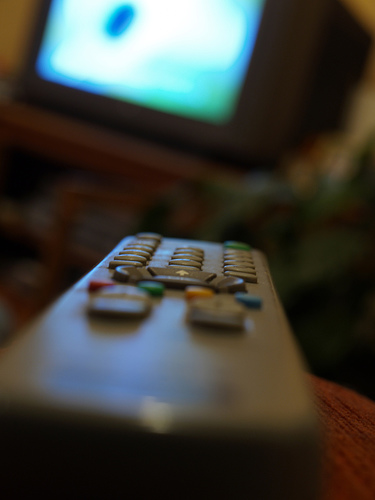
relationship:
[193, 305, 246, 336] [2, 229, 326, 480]
button on remote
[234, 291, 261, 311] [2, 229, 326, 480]
blue button on remote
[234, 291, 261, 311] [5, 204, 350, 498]
blue button on remote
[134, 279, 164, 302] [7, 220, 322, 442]
button on remote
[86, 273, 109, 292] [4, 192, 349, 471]
button on remote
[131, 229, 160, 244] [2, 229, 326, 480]
grey button on remote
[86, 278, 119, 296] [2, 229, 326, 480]
button on remote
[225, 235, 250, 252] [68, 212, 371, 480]
button on remote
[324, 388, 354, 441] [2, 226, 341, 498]
table below remote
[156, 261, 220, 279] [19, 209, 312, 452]
arrow key on remote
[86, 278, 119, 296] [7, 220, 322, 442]
button on remote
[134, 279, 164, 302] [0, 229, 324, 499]
button on remote control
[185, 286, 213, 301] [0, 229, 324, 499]
button on remote control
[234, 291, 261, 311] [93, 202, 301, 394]
blue button on remote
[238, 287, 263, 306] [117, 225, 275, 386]
blue button on remote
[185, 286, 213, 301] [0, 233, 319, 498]
button on remote control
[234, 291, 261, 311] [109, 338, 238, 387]
blue button on control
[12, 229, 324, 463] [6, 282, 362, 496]
remote control on surface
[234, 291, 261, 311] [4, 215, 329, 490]
blue button on remote control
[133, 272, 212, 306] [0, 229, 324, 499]
button on remote control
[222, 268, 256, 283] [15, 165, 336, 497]
grey button on remote control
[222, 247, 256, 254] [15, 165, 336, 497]
grey button on remote control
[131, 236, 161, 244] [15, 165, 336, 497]
grey button on remote control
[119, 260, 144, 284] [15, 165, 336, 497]
grey button on remote control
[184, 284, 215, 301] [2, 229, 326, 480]
button on remote